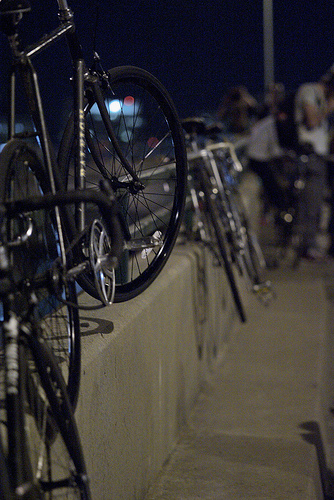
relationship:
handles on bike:
[16, 180, 124, 246] [11, 225, 102, 495]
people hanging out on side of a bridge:
[213, 82, 325, 235] [142, 171, 311, 440]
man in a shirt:
[295, 64, 334, 262] [297, 78, 332, 147]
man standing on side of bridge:
[295, 64, 334, 262] [166, 98, 332, 469]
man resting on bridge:
[295, 64, 334, 262] [106, 166, 329, 445]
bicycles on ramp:
[0, 29, 301, 365] [99, 138, 260, 301]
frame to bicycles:
[3, 18, 84, 153] [0, 0, 187, 418]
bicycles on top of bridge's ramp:
[0, 0, 187, 418] [0, 103, 298, 362]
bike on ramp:
[172, 111, 257, 338] [41, 134, 264, 304]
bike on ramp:
[183, 109, 283, 322] [41, 134, 264, 304]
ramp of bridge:
[41, 134, 264, 304] [53, 131, 332, 441]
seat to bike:
[171, 109, 211, 147] [148, 100, 304, 344]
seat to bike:
[191, 106, 223, 150] [148, 100, 304, 344]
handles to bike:
[0, 180, 124, 246] [4, 182, 175, 495]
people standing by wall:
[261, 63, 331, 223] [218, 131, 306, 298]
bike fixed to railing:
[183, 109, 284, 323] [108, 131, 218, 279]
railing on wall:
[108, 131, 218, 279] [175, 202, 312, 412]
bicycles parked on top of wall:
[0, 0, 187, 418] [31, 231, 227, 495]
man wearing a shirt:
[300, 64, 332, 105] [291, 80, 329, 165]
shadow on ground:
[297, 417, 327, 464] [204, 317, 300, 496]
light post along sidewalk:
[258, 1, 280, 99] [212, 162, 333, 380]